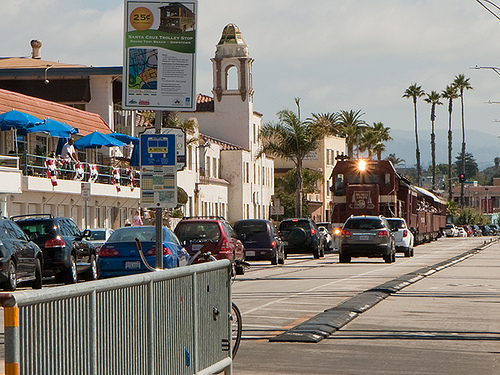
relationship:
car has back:
[338, 213, 396, 263] [342, 225, 387, 250]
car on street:
[333, 209, 398, 267] [308, 253, 417, 283]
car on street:
[278, 216, 327, 260] [227, 234, 497, 373]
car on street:
[233, 217, 286, 267] [227, 234, 497, 373]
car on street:
[176, 216, 246, 277] [227, 234, 497, 373]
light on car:
[375, 230, 388, 237] [338, 215, 397, 265]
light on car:
[343, 230, 351, 238] [338, 215, 397, 265]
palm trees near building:
[400, 81, 426, 185] [441, 185, 498, 225]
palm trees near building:
[422, 88, 444, 190] [447, 179, 497, 225]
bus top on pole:
[137, 132, 178, 213] [151, 110, 164, 265]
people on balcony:
[56, 139, 79, 179] [1, 147, 141, 197]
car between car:
[176, 216, 246, 277] [96, 224, 191, 277]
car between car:
[176, 216, 246, 277] [233, 217, 286, 267]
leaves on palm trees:
[402, 74, 472, 104] [402, 75, 474, 201]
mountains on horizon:
[394, 128, 498, 170] [385, 168, 497, 172]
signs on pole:
[121, 0, 197, 210] [155, 103, 162, 270]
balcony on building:
[2, 160, 142, 196] [0, 87, 142, 232]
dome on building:
[211, 20, 262, 93] [195, 17, 276, 223]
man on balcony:
[59, 137, 77, 177] [23, 140, 145, 198]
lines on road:
[241, 236, 478, 342] [202, 198, 499, 373]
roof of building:
[4, 86, 117, 146] [4, 83, 138, 227]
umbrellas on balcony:
[0, 101, 143, 155] [0, 108, 159, 221]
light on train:
[349, 152, 379, 180] [325, 145, 466, 259]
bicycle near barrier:
[133, 236, 252, 362] [1, 251, 283, 373]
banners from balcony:
[11, 154, 150, 199] [9, 173, 150, 213]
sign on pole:
[73, 177, 101, 197] [69, 180, 106, 236]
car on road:
[87, 203, 207, 313] [202, 198, 499, 373]